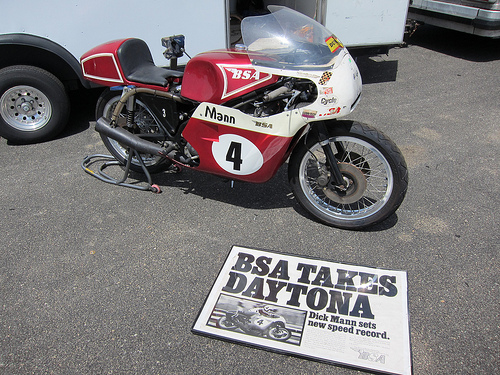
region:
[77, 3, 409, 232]
A red motorcycle.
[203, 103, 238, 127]
A decal on the motorcycle says "Mann".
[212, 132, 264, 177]
A black number 4 in a white oval.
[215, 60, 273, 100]
The initials "BSA".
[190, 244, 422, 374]
A headline reads "BSA takes Daytona".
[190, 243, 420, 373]
A framed news headline page.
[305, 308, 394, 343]
A sub-headline says "Dick Mann sets new speed record."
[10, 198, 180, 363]
The ground is asphalt.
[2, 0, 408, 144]
A trailer is parked behind the motorcycle.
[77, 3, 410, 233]
The motorcycle is red and white.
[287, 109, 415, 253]
This is a wheel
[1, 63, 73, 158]
This is a wheel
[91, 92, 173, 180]
This is a wheel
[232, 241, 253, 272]
This is a letter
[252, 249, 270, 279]
This is a letter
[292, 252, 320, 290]
This is a letter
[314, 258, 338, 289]
This is a letter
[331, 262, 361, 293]
This is a letter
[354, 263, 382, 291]
This is a letter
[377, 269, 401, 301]
This is a letter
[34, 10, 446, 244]
this is a bike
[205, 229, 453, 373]
this is a poster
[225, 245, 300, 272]
letters on the poster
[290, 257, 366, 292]
letters on the poster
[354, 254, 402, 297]
letters on the poster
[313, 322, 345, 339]
letters on the poster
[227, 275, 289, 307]
letters on the poster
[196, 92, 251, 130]
letters on the bike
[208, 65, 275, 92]
letters on the bike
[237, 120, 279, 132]
letters on the bike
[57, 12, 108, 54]
white trailer behind the motorcycle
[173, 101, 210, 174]
motorcycle is red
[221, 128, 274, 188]
4 is in black on side of motorcyle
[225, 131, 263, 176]
4 is in a circle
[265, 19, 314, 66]
motorcycle has a windshield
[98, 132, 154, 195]
bike is on a stand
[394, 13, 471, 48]
trailer is hooked to a vehicle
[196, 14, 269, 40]
door of the trailer is open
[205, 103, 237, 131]
Mann is written on the side of bike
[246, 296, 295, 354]
picture of a motorcycle on the ground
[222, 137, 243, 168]
The number 4 in the white circle on the side of the motorcycle.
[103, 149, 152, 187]
The stand the motorcycle is resting on.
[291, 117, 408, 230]
The front tire of the motorcycle.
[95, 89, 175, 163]
The back tire of the motorcycle.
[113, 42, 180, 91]
The black seat of the motorcycle.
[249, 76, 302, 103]
The handle bars of the motorcycle.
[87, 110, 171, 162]
The tail pipe/muffler of the motorcycle.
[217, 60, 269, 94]
The BSA design on the motorcycle's tank.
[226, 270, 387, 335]
The word Daytona on the frame.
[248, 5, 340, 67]
The windshield window on the motorcycle.